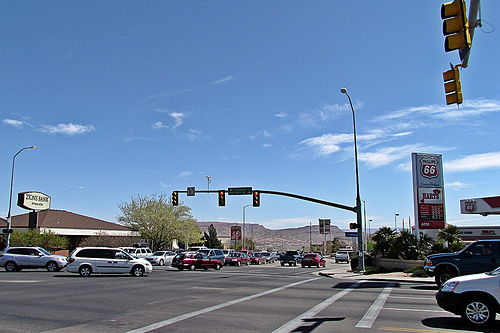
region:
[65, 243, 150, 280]
white minivan in street intersection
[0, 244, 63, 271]
white SUV in street intersection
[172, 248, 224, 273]
red car in street intersection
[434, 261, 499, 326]
white car at stoplight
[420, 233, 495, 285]
blue truck at stoplight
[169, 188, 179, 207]
three way traffic signal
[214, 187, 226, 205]
three way traffic signal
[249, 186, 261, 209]
three way traffic signal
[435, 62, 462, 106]
three way traffic signal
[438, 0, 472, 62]
three way traffic signal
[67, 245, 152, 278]
white minivan in the middle of the intersecion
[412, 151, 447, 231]
sign with gas prices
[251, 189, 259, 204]
rightmost traffic light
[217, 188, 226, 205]
middle traffic light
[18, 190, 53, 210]
restaurant sign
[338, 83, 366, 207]
traffic light on the corner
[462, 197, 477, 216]
Phillips 66 sign on gas station awning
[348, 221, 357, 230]
digital Don't Walk sign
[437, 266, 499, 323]
front of white car waiting at intersection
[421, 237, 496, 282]
front of blue SUV waiting at intersectio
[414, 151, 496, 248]
Phillips 66 gas station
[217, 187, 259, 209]
two red traffic lights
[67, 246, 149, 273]
white minivan in the interesection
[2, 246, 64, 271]
silver SUV in the intersection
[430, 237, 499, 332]
blue truck and white car stopped at intersection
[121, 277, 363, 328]
white lines of crosswalk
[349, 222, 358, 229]
red do not cross sign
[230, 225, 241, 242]
orange Home Depot sign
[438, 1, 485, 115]
two traffic lights on the right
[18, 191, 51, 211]
Sign for the bank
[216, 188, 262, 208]
two red stop lights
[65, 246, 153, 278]
white van in center of intersection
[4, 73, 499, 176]
wispy clouds in blue sky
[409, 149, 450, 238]
large red and white sign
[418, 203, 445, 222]
prices for gas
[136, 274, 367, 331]
a pedestrian crosswalk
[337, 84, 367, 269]
street light connected to stop lights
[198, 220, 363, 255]
mountains in background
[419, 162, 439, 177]
white colored number 66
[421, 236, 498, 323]
two cars stopped at intersection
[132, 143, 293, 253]
traffic light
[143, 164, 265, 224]
traffic light